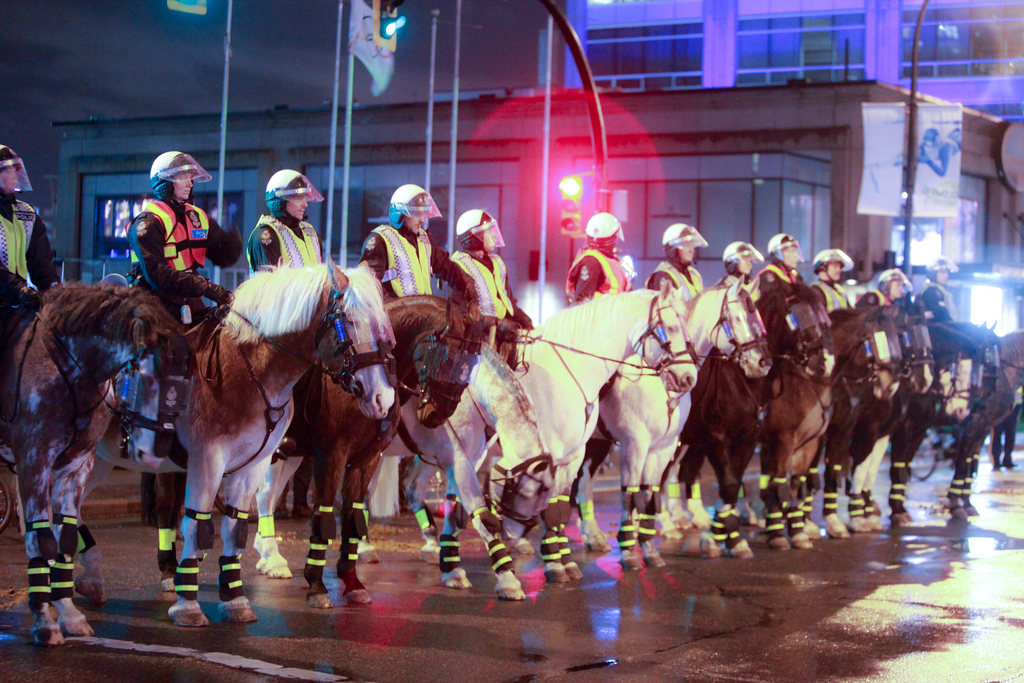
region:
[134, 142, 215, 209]
the head of a man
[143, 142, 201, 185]
the helmet of a man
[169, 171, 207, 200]
the face of a man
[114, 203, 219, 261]
the vest of a man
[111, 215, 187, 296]
the right arm of a man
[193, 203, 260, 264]
the left arm of a man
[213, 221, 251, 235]
the arm of a man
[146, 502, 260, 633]
the front legs of a horse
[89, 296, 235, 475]
Head of a brown horse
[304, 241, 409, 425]
Head of a horse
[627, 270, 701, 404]
Head of a white horse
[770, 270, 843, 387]
Head of a brown horse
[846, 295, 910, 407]
Head of a horse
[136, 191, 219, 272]
Orange and yellow vest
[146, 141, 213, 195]
Helmet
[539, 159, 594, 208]
Street light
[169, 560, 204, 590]
two bright yellow stripes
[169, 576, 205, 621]
a horse's hoof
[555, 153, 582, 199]
a light shining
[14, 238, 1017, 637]
a row of horses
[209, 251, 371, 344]
long white hair on the neck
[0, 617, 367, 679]
white line on the ground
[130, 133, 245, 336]
person wearing a vest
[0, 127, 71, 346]
person sitting on top of a horse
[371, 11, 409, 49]
traffic light shining green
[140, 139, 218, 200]
helmet on the head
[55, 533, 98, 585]
leg of the horse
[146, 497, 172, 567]
leg of the horse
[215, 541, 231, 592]
leg of the horse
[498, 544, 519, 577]
leg of the horse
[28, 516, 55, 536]
yellow reflecting strip on horse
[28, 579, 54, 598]
yellow reflecting strip on horse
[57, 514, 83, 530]
yellow reflecting strip on horse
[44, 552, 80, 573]
yellow reflecting strip on horse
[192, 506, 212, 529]
yellow reflecting strip on horse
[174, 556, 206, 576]
yellow reflecting strip on horse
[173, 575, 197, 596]
yellow reflecting strip on horse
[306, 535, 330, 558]
yellow reflecting strip on horse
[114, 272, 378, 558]
a horse on the road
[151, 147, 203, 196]
person has a head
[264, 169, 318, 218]
person has a head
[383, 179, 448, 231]
person has a head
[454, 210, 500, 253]
person has a head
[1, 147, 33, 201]
person has a head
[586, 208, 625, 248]
person has a head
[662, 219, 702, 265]
person has a head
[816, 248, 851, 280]
person has a head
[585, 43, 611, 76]
glass window on the building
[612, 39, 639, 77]
glass window on the building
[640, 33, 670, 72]
glass window on the building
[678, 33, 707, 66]
glass window on the building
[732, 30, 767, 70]
glass window on the building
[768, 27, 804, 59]
glass window on the building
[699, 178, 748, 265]
glass window on the building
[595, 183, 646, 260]
glass window on the building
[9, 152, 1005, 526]
people on the horses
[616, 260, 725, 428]
head of the horse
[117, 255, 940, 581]
white and brown horses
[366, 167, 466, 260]
helmet on the man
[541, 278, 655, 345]
white hair on horse